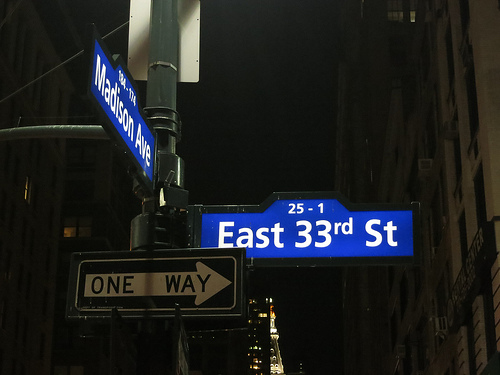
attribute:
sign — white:
[86, 23, 156, 190]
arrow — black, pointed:
[82, 264, 232, 303]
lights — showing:
[386, 1, 418, 25]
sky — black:
[92, 9, 392, 373]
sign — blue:
[84, 22, 178, 190]